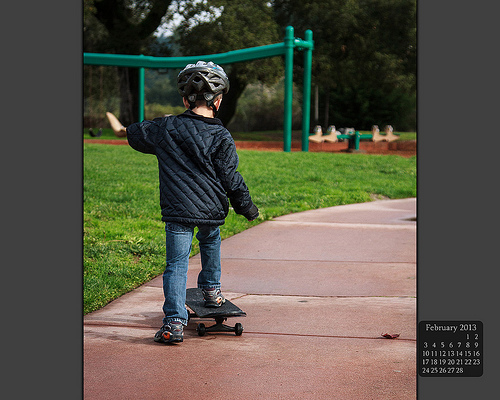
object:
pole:
[300, 28, 314, 152]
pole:
[282, 25, 294, 153]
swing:
[87, 65, 103, 137]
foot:
[151, 313, 189, 345]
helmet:
[174, 60, 231, 104]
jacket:
[127, 116, 259, 224]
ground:
[433, 135, 480, 182]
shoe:
[200, 284, 227, 308]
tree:
[82, 0, 172, 127]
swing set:
[82, 26, 315, 154]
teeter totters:
[336, 125, 401, 153]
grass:
[256, 157, 356, 202]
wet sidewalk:
[85, 194, 415, 398]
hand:
[213, 127, 263, 218]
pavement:
[80, 198, 417, 400]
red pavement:
[266, 226, 416, 369]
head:
[180, 79, 224, 109]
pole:
[138, 54, 146, 123]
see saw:
[308, 119, 405, 150]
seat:
[384, 124, 401, 143]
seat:
[370, 124, 383, 142]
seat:
[326, 125, 340, 144]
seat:
[309, 125, 324, 144]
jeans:
[162, 222, 223, 323]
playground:
[79, 129, 416, 154]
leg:
[196, 226, 226, 308]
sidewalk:
[82, 194, 417, 399]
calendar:
[415, 319, 485, 379]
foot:
[196, 279, 226, 309]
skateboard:
[185, 286, 246, 337]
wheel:
[196, 322, 206, 337]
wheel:
[234, 322, 244, 336]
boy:
[119, 57, 266, 345]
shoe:
[152, 319, 185, 343]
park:
[87, 7, 411, 387]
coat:
[123, 108, 260, 227]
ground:
[82, 133, 413, 399]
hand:
[94, 105, 135, 144]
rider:
[105, 54, 265, 346]